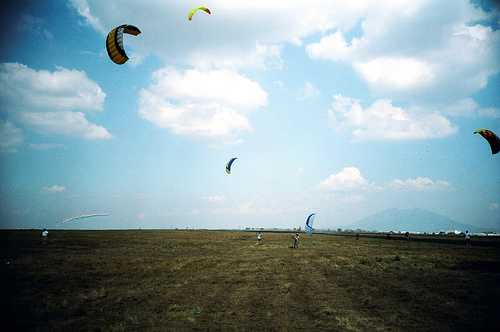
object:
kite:
[105, 23, 142, 66]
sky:
[0, 0, 497, 232]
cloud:
[137, 65, 269, 145]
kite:
[187, 5, 213, 21]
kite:
[224, 156, 238, 175]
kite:
[471, 128, 499, 155]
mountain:
[344, 206, 495, 233]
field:
[2, 228, 497, 331]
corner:
[0, 1, 29, 38]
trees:
[333, 228, 344, 234]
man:
[41, 227, 50, 245]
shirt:
[41, 230, 49, 236]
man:
[291, 232, 302, 249]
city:
[390, 228, 497, 236]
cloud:
[11, 107, 115, 140]